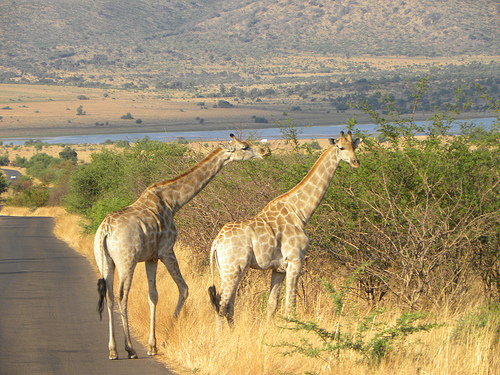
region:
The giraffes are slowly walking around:
[26, 41, 476, 353]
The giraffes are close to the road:
[15, 40, 490, 340]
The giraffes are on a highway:
[20, 32, 462, 368]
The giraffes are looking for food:
[1, 40, 477, 362]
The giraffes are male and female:
[16, 57, 447, 364]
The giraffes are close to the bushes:
[10, 60, 473, 356]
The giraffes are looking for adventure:
[6, 22, 481, 363]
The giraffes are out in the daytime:
[5, 48, 490, 361]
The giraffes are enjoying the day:
[22, 37, 467, 362]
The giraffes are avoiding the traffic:
[8, 39, 478, 362]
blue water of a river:
[6, 115, 497, 147]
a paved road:
[3, 211, 160, 371]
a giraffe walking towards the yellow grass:
[89, 130, 269, 360]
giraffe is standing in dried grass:
[207, 125, 359, 332]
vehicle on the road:
[7, 171, 15, 181]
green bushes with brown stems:
[351, 118, 497, 306]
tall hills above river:
[8, 3, 490, 125]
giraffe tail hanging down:
[204, 245, 224, 313]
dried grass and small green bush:
[188, 324, 488, 367]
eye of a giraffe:
[237, 145, 251, 152]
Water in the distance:
[0, 115, 497, 146]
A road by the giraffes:
[0, 215, 174, 372]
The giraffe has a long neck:
[278, 150, 340, 215]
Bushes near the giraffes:
[66, 159, 497, 374]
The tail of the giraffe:
[96, 231, 108, 307]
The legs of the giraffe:
[107, 268, 137, 361]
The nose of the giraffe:
[348, 156, 361, 163]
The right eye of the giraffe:
[336, 145, 347, 151]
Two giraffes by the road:
[93, 132, 360, 360]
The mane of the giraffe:
[150, 148, 220, 188]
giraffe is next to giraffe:
[210, 127, 361, 334]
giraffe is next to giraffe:
[92, 134, 269, 361]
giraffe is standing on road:
[2, 216, 180, 373]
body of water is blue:
[1, 118, 497, 138]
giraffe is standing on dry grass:
[206, 129, 360, 344]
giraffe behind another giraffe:
[94, 129, 273, 363]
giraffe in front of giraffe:
[211, 128, 362, 372]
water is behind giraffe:
[1, 112, 498, 140]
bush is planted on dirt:
[74, 104, 87, 118]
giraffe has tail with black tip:
[96, 278, 106, 320]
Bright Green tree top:
[384, 82, 457, 182]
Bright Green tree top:
[120, 140, 192, 162]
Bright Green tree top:
[260, 144, 323, 189]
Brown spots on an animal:
[311, 164, 340, 192]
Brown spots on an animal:
[297, 179, 329, 208]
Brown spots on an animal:
[280, 188, 325, 234]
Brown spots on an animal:
[262, 204, 290, 251]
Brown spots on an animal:
[171, 166, 211, 198]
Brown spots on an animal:
[132, 197, 164, 220]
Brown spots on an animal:
[99, 204, 138, 254]